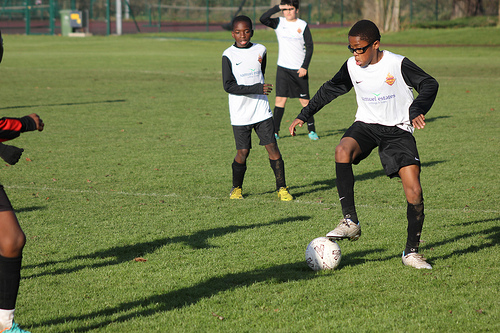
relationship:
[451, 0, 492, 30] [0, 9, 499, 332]
tree trunk behind a courts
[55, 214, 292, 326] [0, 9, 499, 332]
shadows in courts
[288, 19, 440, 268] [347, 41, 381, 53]
boy wearing glasses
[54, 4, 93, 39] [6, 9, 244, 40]
garbage cans on courts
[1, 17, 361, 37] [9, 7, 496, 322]
walkway on courts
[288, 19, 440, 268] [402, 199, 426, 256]
boy wearing shinguards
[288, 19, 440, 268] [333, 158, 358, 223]
boy wearing shinguards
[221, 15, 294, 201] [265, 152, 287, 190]
body wearing shinguards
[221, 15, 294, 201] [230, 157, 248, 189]
body wearing shinguards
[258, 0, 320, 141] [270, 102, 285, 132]
boy wearing shinguards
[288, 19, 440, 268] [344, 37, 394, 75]
boy wearing glasses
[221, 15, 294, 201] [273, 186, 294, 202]
body wearing shoe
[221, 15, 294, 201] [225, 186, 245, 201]
body wearing shoe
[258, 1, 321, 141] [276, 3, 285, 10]
boy has hand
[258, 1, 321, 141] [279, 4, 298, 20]
boy has face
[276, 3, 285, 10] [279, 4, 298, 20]
hand on face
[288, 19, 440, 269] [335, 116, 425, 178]
boy wearing shorts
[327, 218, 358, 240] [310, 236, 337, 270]
foot on ball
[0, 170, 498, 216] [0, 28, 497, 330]
white line on grass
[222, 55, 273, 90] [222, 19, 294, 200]
hand in front of body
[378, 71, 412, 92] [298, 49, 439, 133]
logo on jersey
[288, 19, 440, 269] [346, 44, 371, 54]
boy wearing glasses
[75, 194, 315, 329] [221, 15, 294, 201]
shadows of body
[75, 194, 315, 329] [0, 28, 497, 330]
shadows in grass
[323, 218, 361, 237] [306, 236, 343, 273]
foot on ball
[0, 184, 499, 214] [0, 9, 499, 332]
white line on courts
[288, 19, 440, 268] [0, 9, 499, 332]
boy on courts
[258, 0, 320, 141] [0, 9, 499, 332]
boy on courts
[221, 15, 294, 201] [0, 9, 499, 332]
body on courts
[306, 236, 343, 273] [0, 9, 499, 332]
ball on courts